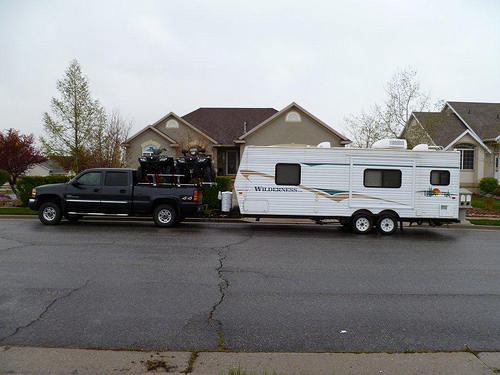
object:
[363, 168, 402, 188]
black window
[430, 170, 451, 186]
black window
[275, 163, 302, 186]
black window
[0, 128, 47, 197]
tree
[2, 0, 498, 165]
sky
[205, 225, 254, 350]
crack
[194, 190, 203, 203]
light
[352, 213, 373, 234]
wheel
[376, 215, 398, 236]
wheel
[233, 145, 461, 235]
camper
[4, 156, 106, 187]
house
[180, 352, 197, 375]
crack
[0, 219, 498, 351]
road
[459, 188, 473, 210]
mail box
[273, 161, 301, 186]
window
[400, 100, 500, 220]
house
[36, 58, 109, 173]
tree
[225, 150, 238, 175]
door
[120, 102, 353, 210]
house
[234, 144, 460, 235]
rv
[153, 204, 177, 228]
back wheels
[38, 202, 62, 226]
wheel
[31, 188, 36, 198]
headlight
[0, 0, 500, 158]
cloud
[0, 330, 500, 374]
grass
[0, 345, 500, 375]
sidewalk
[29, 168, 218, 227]
pickup truck